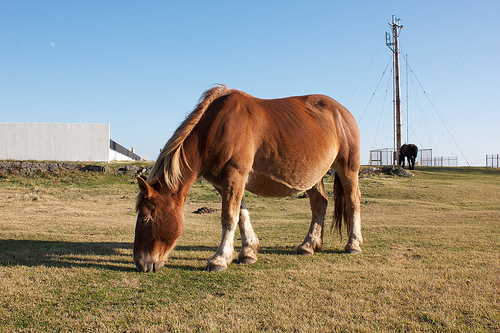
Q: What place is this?
A: It is a pasture.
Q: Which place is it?
A: It is a pasture.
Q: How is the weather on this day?
A: It is clear.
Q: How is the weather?
A: It is clear.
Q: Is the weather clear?
A: Yes, it is clear.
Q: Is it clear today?
A: Yes, it is clear.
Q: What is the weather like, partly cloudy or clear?
A: It is clear.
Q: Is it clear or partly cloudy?
A: It is clear.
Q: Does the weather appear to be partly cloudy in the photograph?
A: No, it is clear.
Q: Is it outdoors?
A: Yes, it is outdoors.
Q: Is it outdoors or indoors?
A: It is outdoors.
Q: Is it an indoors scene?
A: No, it is outdoors.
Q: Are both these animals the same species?
A: Yes, all the animals are horses.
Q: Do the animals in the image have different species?
A: No, all the animals are horses.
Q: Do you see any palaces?
A: No, there are no palaces.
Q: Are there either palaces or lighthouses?
A: No, there are no palaces or lighthouses.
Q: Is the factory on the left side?
A: Yes, the factory is on the left of the image.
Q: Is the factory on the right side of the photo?
A: No, the factory is on the left of the image.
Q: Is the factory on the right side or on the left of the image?
A: The factory is on the left of the image.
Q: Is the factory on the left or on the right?
A: The factory is on the left of the image.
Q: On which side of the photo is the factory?
A: The factory is on the left of the image.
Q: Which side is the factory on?
A: The factory is on the left of the image.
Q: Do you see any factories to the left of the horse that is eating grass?
A: Yes, there is a factory to the left of the horse.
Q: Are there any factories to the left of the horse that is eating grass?
A: Yes, there is a factory to the left of the horse.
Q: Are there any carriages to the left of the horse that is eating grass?
A: No, there is a factory to the left of the horse.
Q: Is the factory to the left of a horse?
A: Yes, the factory is to the left of a horse.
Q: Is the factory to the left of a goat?
A: No, the factory is to the left of a horse.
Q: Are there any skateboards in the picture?
A: No, there are no skateboards.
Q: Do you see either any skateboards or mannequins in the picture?
A: No, there are no skateboards or mannequins.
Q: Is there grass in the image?
A: Yes, there is grass.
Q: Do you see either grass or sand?
A: Yes, there is grass.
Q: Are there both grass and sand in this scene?
A: No, there is grass but no sand.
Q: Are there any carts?
A: No, there are no carts.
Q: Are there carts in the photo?
A: No, there are no carts.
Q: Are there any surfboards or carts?
A: No, there are no carts or surfboards.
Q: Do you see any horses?
A: Yes, there is a horse.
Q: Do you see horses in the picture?
A: Yes, there is a horse.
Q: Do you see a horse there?
A: Yes, there is a horse.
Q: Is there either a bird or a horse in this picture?
A: Yes, there is a horse.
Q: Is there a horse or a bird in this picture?
A: Yes, there is a horse.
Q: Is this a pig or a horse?
A: This is a horse.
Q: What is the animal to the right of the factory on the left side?
A: The animal is a horse.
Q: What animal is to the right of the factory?
A: The animal is a horse.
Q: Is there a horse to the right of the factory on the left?
A: Yes, there is a horse to the right of the factory.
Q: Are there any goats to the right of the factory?
A: No, there is a horse to the right of the factory.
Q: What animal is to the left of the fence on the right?
A: The animal is a horse.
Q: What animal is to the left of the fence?
A: The animal is a horse.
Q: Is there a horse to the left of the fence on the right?
A: Yes, there is a horse to the left of the fence.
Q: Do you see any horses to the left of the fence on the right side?
A: Yes, there is a horse to the left of the fence.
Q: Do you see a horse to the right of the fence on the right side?
A: No, the horse is to the left of the fence.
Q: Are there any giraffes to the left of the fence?
A: No, there is a horse to the left of the fence.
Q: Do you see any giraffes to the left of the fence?
A: No, there is a horse to the left of the fence.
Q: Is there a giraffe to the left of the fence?
A: No, there is a horse to the left of the fence.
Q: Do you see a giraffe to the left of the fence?
A: No, there is a horse to the left of the fence.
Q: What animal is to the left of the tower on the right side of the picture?
A: The animal is a horse.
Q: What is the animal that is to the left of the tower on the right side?
A: The animal is a horse.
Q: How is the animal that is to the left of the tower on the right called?
A: The animal is a horse.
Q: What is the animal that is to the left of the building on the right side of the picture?
A: The animal is a horse.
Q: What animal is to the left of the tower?
A: The animal is a horse.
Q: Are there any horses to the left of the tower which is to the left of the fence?
A: Yes, there is a horse to the left of the tower.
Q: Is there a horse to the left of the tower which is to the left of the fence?
A: Yes, there is a horse to the left of the tower.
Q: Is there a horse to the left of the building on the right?
A: Yes, there is a horse to the left of the tower.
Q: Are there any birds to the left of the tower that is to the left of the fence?
A: No, there is a horse to the left of the tower.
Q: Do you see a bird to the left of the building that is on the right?
A: No, there is a horse to the left of the tower.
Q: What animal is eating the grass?
A: The animal is a horse.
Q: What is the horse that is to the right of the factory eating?
A: The horse is eating grass.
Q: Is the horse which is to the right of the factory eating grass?
A: Yes, the horse is eating grass.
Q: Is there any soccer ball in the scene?
A: No, there are no soccer balls.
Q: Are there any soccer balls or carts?
A: No, there are no soccer balls or carts.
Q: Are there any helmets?
A: No, there are no helmets.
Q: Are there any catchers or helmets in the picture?
A: No, there are no helmets or catchers.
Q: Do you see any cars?
A: No, there are no cars.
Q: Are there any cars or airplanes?
A: No, there are no cars or airplanes.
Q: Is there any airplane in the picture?
A: No, there are no airplanes.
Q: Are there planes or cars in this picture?
A: No, there are no planes or cars.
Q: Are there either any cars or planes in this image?
A: No, there are no planes or cars.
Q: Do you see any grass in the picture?
A: Yes, there is grass.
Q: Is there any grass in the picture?
A: Yes, there is grass.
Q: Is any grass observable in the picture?
A: Yes, there is grass.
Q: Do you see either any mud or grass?
A: Yes, there is grass.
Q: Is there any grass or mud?
A: Yes, there is grass.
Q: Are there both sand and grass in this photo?
A: No, there is grass but no sand.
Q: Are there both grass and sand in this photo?
A: No, there is grass but no sand.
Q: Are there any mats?
A: No, there are no mats.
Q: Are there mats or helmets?
A: No, there are no mats or helmets.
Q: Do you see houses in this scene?
A: No, there are no houses.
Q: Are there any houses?
A: No, there are no houses.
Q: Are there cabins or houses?
A: No, there are no houses or cabins.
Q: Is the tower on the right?
A: Yes, the tower is on the right of the image.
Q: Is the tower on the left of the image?
A: No, the tower is on the right of the image.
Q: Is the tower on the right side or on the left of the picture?
A: The tower is on the right of the image.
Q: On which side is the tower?
A: The tower is on the right of the image.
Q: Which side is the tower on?
A: The tower is on the right of the image.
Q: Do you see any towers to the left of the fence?
A: Yes, there is a tower to the left of the fence.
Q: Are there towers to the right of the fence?
A: No, the tower is to the left of the fence.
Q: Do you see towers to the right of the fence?
A: No, the tower is to the left of the fence.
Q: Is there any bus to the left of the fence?
A: No, there is a tower to the left of the fence.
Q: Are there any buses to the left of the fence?
A: No, there is a tower to the left of the fence.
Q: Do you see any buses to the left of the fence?
A: No, there is a tower to the left of the fence.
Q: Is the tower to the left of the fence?
A: Yes, the tower is to the left of the fence.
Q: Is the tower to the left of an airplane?
A: No, the tower is to the left of the fence.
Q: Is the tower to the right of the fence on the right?
A: No, the tower is to the left of the fence.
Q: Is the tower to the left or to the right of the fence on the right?
A: The tower is to the left of the fence.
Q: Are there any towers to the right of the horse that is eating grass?
A: Yes, there is a tower to the right of the horse.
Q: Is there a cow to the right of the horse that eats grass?
A: No, there is a tower to the right of the horse.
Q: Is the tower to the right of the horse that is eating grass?
A: Yes, the tower is to the right of the horse.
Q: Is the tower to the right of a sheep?
A: No, the tower is to the right of the horse.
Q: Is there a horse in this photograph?
A: Yes, there is a horse.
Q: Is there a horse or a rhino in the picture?
A: Yes, there is a horse.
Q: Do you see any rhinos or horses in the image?
A: Yes, there is a horse.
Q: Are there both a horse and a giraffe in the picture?
A: No, there is a horse but no giraffes.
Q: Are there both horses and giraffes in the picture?
A: No, there is a horse but no giraffes.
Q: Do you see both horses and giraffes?
A: No, there is a horse but no giraffes.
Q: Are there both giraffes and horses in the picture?
A: No, there is a horse but no giraffes.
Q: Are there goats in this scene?
A: No, there are no goats.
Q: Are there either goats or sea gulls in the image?
A: No, there are no goats or sea gulls.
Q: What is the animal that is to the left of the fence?
A: The animal is a horse.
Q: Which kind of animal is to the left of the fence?
A: The animal is a horse.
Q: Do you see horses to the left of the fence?
A: Yes, there is a horse to the left of the fence.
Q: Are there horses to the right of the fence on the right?
A: No, the horse is to the left of the fence.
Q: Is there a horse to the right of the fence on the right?
A: No, the horse is to the left of the fence.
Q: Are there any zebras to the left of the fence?
A: No, there is a horse to the left of the fence.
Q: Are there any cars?
A: No, there are no cars.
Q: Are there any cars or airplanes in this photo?
A: No, there are no cars or airplanes.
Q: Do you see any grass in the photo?
A: Yes, there is grass.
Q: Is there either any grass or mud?
A: Yes, there is grass.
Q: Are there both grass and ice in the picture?
A: No, there is grass but no ice.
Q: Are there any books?
A: No, there are no books.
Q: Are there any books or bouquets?
A: No, there are no books or bouquets.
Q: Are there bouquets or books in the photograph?
A: No, there are no books or bouquets.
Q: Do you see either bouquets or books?
A: No, there are no books or bouquets.